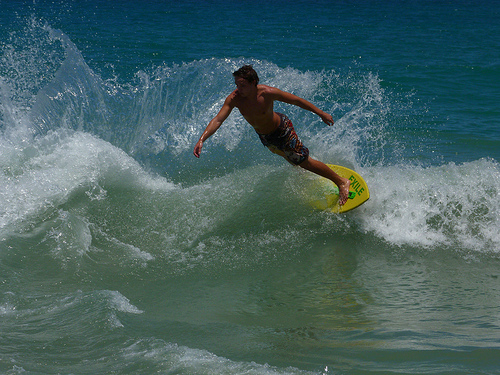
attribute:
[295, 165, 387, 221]
surf board — yellow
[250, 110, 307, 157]
swimming trunks — multicolored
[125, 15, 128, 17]
water drop —  in air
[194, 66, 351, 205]
man — young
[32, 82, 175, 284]
water — drop in air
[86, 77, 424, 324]
water — large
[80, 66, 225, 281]
deep water — deeper